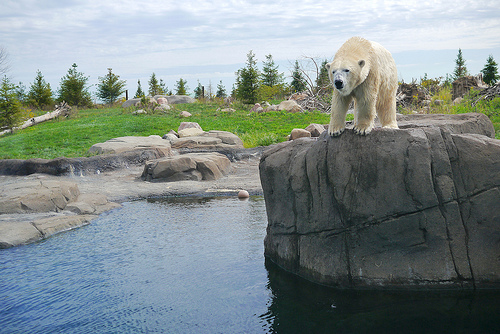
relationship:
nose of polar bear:
[333, 80, 345, 90] [327, 36, 399, 136]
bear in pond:
[317, 30, 412, 136] [4, 185, 288, 330]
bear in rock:
[323, 36, 400, 136] [254, 105, 499, 295]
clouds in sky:
[25, 6, 469, 65] [5, 8, 490, 78]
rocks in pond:
[4, 131, 246, 248] [0, 188, 499, 333]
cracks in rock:
[364, 193, 489, 260] [224, 110, 493, 296]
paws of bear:
[321, 120, 374, 141] [317, 15, 411, 141]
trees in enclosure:
[2, 48, 323, 113] [5, 49, 497, 329]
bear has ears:
[323, 36, 400, 136] [322, 58, 366, 68]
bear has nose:
[323, 36, 400, 136] [333, 77, 345, 91]